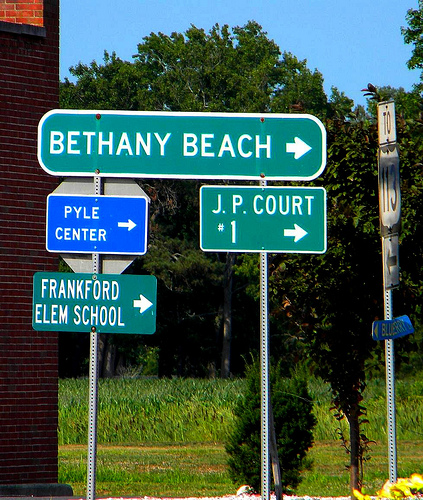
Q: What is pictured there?
A: Signs.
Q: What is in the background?
A: Trees.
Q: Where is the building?
A: Left.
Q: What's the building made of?
A: Bricks.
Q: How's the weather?
A: Clear.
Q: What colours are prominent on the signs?
A: Green, white.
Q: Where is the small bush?
A: Behind the sign.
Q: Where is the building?
A: To the left.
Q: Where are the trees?
A: In the background on signs.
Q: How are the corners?
A: Rounded.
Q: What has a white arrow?
A: The sign.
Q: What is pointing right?
A: The arrow.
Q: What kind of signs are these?
A: Street signs.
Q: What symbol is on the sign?
A: Arrow.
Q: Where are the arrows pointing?
A: Right.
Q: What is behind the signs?
A: Trees.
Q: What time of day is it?
A: Daytime.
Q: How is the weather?
A: Sunny.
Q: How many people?
A: None.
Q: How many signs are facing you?
A: Four.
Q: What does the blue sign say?
A: Pyle Center.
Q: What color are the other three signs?
A: Green.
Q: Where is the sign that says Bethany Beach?
A: At the very top.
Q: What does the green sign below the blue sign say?
A: Frankford Elem school.